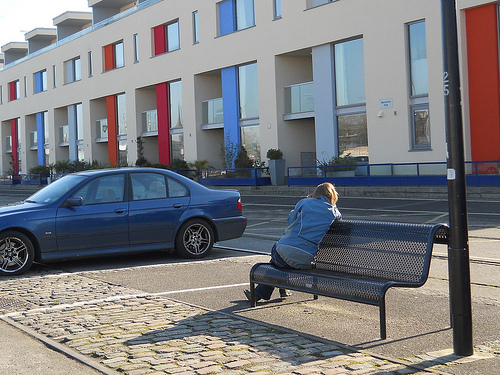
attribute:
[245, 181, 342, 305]
woman — person, sitting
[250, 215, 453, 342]
bench — metal, modern, black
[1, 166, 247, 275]
car — parked, blue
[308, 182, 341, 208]
hair — light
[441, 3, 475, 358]
pole — metal, black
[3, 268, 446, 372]
ground — stone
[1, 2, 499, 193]
building — colorful, tan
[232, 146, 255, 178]
bush — green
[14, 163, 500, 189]
fence — metal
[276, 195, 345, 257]
jacket — light blue, blue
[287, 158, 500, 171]
railing — metal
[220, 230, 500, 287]
sidewalk — paved, concrete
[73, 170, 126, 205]
window — closed